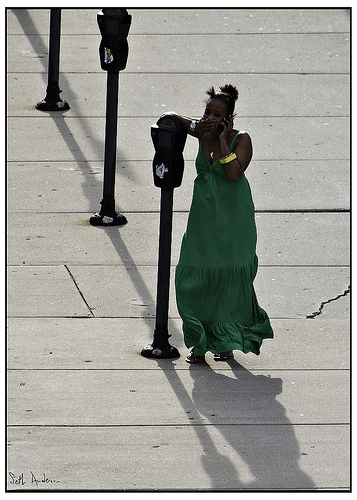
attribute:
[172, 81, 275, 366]
woman — leaning, black, astonished, surprised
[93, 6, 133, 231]
meter — black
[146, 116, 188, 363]
meter — tall, black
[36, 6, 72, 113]
pole — black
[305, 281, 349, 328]
crack — long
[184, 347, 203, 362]
flip flop — black, open, favorite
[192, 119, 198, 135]
wrist watch — silver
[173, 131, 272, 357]
dress — green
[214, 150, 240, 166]
bracelet — yellow, gold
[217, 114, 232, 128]
phone — cell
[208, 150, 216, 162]
necklace — silver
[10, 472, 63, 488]
signature — written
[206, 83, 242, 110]
hair — up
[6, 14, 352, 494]
ground — cement, concrete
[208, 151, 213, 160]
pendant — silver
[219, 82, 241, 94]
bun — hairstyle